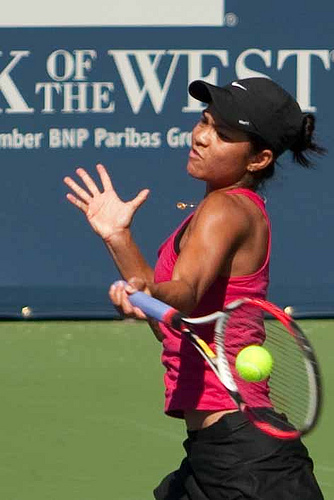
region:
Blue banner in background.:
[4, 5, 333, 324]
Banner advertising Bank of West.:
[0, 1, 331, 156]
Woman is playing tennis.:
[58, 70, 324, 498]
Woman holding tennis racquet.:
[108, 275, 322, 442]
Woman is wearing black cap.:
[170, 65, 318, 166]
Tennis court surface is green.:
[0, 321, 329, 496]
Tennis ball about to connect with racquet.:
[105, 273, 333, 444]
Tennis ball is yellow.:
[226, 337, 280, 396]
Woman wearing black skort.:
[144, 402, 329, 495]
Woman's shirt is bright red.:
[134, 187, 293, 415]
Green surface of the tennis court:
[15, 338, 114, 434]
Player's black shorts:
[189, 440, 311, 495]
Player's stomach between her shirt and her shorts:
[185, 413, 220, 429]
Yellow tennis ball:
[231, 340, 276, 386]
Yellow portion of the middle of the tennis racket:
[193, 337, 221, 363]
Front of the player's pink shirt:
[169, 344, 195, 404]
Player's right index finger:
[93, 159, 115, 193]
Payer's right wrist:
[100, 232, 141, 259]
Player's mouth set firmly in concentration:
[185, 143, 209, 163]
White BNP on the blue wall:
[48, 123, 89, 153]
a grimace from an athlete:
[162, 67, 323, 195]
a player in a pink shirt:
[55, 71, 322, 494]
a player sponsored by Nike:
[50, 72, 332, 491]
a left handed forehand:
[50, 64, 328, 490]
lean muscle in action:
[92, 179, 278, 319]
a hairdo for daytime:
[167, 63, 326, 197]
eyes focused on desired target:
[133, 71, 311, 189]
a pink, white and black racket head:
[214, 292, 325, 443]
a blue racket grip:
[96, 265, 197, 346]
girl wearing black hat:
[176, 62, 318, 221]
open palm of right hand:
[53, 88, 158, 256]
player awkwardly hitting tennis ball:
[63, 77, 326, 431]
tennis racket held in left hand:
[99, 257, 325, 442]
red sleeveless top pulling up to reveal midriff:
[135, 162, 276, 444]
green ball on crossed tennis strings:
[206, 337, 287, 394]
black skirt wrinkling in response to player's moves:
[140, 395, 322, 485]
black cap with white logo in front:
[176, 56, 310, 175]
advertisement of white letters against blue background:
[2, 37, 316, 161]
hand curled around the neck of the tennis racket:
[102, 259, 183, 332]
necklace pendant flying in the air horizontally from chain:
[167, 177, 256, 217]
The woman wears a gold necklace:
[139, 100, 327, 263]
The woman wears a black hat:
[98, 74, 331, 162]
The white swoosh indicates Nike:
[185, 55, 332, 137]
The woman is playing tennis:
[101, 109, 321, 424]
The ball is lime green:
[128, 298, 313, 430]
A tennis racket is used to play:
[64, 255, 329, 447]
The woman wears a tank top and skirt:
[133, 279, 304, 492]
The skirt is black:
[167, 421, 319, 494]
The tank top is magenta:
[138, 214, 281, 409]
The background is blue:
[17, 112, 330, 339]